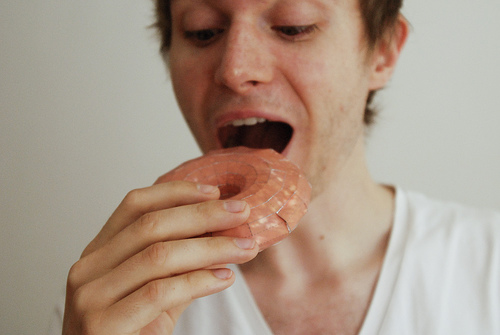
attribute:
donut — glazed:
[153, 147, 313, 252]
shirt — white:
[170, 184, 500, 334]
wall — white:
[2, 1, 500, 332]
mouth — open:
[210, 107, 299, 158]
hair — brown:
[150, 0, 402, 129]